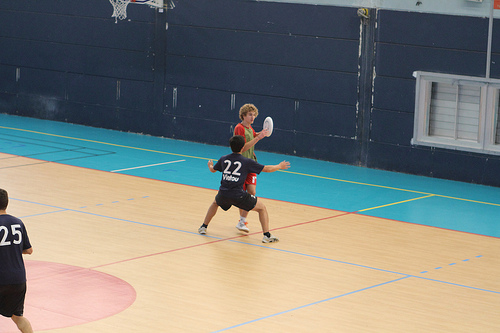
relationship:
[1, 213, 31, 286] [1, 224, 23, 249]
shirt has numbers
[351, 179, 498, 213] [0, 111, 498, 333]
line on floor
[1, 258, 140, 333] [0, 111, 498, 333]
circle on floor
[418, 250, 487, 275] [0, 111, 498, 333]
line on floor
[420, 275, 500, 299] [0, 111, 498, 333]
line on floor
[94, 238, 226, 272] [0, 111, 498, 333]
line on basketball court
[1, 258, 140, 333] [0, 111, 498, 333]
circle on court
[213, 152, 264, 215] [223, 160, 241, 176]
jersey has numbers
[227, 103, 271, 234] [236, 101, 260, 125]
frisbee player has head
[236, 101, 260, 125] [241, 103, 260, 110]
head has hair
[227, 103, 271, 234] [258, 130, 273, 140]
frisbee player has hand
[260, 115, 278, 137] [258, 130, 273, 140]
frisbee in hand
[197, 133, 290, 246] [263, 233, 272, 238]
man wearing sock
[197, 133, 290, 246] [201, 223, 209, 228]
man wearing sock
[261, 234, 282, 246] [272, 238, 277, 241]
sneaker has trim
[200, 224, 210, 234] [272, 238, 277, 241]
sneaker has trim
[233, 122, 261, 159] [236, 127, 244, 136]
shirt has sleeve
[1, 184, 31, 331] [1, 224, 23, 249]
boy wearing number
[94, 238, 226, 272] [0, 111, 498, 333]
line on court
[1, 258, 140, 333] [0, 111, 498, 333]
shape on floor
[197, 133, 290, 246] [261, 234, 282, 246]
kid has shoe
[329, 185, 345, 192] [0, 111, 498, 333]
paint on floor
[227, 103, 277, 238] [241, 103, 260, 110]
boy has hair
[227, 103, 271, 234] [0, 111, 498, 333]
frisbee player on basketball court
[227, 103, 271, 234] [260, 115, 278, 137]
frisbee player has frisbee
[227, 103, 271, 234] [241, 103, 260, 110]
frisbee player has hair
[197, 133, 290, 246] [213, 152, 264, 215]
man has shirt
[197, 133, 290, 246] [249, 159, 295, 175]
man has arm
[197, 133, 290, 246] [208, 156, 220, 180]
man has arm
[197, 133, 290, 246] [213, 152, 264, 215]
man in shirt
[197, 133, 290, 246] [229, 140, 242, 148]
man has hair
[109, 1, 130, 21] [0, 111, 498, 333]
net above court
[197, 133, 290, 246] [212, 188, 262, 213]
man wearing shorts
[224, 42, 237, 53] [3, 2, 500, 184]
paint on wall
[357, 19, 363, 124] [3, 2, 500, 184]
marks on wall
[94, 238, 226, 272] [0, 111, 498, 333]
line on floor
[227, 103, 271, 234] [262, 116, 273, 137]
frisbee player holding frisbee